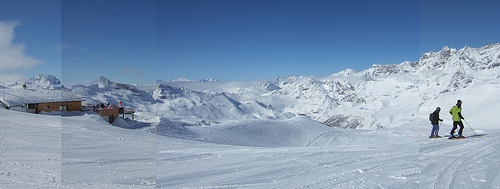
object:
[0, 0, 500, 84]
sky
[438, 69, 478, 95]
mountains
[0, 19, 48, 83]
cloud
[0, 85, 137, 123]
building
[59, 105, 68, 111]
window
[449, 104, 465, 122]
jacket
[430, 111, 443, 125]
arms down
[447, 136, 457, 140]
skis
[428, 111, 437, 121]
backpack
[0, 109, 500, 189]
ground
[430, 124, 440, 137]
pants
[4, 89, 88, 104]
roof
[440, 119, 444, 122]
right hand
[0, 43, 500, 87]
ridge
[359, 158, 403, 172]
tracks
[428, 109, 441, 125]
jacket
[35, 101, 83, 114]
side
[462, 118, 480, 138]
ski pole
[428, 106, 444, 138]
person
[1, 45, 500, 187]
snow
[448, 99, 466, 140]
person